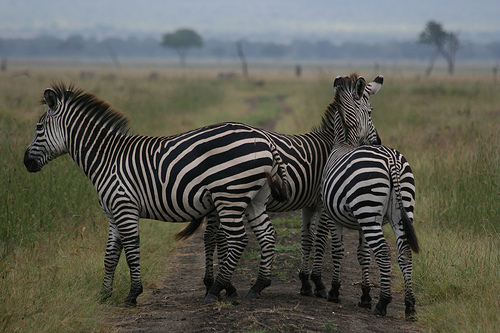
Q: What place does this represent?
A: It represents the path.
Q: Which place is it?
A: It is a path.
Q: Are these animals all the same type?
A: Yes, all the animals are zebras.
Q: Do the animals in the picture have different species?
A: No, all the animals are zebras.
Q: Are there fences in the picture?
A: No, there are no fences.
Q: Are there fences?
A: No, there are no fences.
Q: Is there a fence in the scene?
A: No, there are no fences.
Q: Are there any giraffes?
A: No, there are no giraffes.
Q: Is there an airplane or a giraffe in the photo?
A: No, there are no giraffes or airplanes.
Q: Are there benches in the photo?
A: No, there are no benches.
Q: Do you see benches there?
A: No, there are no benches.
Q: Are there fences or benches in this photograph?
A: No, there are no benches or fences.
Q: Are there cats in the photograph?
A: No, there are no cats.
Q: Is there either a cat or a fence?
A: No, there are no cats or fences.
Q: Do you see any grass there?
A: Yes, there is grass.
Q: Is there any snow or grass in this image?
A: Yes, there is grass.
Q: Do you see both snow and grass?
A: No, there is grass but no snow.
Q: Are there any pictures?
A: No, there are no pictures.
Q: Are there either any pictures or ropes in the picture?
A: No, there are no pictures or ropes.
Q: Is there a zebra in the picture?
A: Yes, there is a zebra.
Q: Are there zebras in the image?
A: Yes, there is a zebra.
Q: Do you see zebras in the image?
A: Yes, there is a zebra.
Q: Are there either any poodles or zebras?
A: Yes, there is a zebra.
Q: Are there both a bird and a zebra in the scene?
A: No, there is a zebra but no birds.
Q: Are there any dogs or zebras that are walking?
A: Yes, the zebra is walking.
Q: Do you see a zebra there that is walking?
A: Yes, there is a zebra that is walking.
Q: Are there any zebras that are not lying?
A: Yes, there is a zebra that is walking.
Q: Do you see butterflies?
A: No, there are no butterflies.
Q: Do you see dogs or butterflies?
A: No, there are no butterflies or dogs.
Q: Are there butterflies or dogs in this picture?
A: No, there are no butterflies or dogs.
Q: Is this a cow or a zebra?
A: This is a zebra.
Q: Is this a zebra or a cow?
A: This is a zebra.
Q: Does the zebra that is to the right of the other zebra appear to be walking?
A: Yes, the zebra is walking.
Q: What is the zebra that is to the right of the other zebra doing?
A: The zebra is walking.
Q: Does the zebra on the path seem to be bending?
A: No, the zebra is walking.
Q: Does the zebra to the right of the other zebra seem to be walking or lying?
A: The zebra is walking.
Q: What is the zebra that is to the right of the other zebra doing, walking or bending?
A: The zebra is walking.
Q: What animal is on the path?
A: The zebra is on the path.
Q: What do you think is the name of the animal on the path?
A: The animal is a zebra.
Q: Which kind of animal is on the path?
A: The animal is a zebra.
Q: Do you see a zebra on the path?
A: Yes, there is a zebra on the path.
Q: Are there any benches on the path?
A: No, there is a zebra on the path.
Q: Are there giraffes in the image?
A: No, there are no giraffes.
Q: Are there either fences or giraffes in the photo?
A: No, there are no giraffes or fences.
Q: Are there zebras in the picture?
A: Yes, there is a zebra.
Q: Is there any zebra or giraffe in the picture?
A: Yes, there is a zebra.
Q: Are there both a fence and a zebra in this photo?
A: No, there is a zebra but no fences.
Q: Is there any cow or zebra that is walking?
A: Yes, the zebra is walking.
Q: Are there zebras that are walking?
A: Yes, there is a zebra that is walking.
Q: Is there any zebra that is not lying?
A: Yes, there is a zebra that is walking.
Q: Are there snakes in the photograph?
A: No, there are no snakes.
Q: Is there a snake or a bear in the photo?
A: No, there are no snakes or bears.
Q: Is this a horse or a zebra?
A: This is a zebra.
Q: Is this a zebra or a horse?
A: This is a zebra.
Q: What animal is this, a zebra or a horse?
A: This is a zebra.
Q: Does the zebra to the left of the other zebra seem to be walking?
A: Yes, the zebra is walking.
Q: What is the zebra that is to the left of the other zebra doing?
A: The zebra is walking.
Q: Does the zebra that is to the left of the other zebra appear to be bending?
A: No, the zebra is walking.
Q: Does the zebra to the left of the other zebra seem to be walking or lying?
A: The zebra is walking.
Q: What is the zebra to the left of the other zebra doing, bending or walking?
A: The zebra is walking.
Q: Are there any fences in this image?
A: No, there are no fences.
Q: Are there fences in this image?
A: No, there are no fences.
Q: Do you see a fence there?
A: No, there are no fences.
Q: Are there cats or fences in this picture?
A: No, there are no fences or cats.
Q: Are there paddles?
A: No, there are no paddles.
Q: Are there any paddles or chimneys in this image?
A: No, there are no paddles or chimneys.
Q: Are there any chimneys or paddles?
A: No, there are no paddles or chimneys.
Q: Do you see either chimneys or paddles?
A: No, there are no paddles or chimneys.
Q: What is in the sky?
A: The clouds are in the sky.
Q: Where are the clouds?
A: The clouds are in the sky.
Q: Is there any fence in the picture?
A: No, there are no fences.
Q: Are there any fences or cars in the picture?
A: No, there are no fences or cars.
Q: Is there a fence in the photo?
A: No, there are no fences.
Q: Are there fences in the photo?
A: No, there are no fences.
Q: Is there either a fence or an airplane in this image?
A: No, there are no fences or airplanes.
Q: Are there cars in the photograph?
A: No, there are no cars.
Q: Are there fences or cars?
A: No, there are no cars or fences.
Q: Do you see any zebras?
A: Yes, there is a zebra.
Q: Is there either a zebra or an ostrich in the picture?
A: Yes, there is a zebra.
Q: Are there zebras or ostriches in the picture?
A: Yes, there is a zebra.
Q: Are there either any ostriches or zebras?
A: Yes, there is a zebra.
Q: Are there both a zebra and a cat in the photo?
A: No, there is a zebra but no cats.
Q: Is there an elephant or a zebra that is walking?
A: Yes, the zebra is walking.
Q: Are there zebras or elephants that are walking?
A: Yes, the zebra is walking.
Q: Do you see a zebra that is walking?
A: Yes, there is a zebra that is walking.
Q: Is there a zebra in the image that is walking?
A: Yes, there is a zebra that is walking.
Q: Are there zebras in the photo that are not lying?
A: Yes, there is a zebra that is walking.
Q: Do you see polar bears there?
A: No, there are no polar bears.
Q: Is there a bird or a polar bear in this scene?
A: No, there are no polar bears or birds.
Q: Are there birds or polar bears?
A: No, there are no polar bears or birds.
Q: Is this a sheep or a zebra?
A: This is a zebra.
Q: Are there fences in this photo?
A: No, there are no fences.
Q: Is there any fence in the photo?
A: No, there are no fences.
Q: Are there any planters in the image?
A: No, there are no planters.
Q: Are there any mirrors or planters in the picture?
A: No, there are no planters or mirrors.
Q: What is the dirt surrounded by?
A: The dirt is surrounded by the grass.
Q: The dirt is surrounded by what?
A: The dirt is surrounded by the grass.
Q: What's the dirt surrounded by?
A: The dirt is surrounded by the grass.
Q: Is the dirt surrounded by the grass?
A: Yes, the dirt is surrounded by the grass.